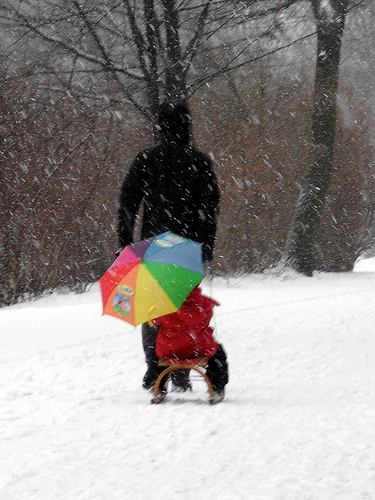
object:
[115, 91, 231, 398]
he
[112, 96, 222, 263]
jacket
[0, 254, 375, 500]
snow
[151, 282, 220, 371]
jacket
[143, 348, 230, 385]
pants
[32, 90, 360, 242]
snowfall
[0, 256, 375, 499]
ground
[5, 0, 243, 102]
trees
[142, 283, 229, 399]
child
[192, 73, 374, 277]
vegetation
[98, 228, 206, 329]
umbrella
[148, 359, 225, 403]
sled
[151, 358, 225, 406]
bench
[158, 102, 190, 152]
mask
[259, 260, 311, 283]
pile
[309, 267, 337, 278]
pile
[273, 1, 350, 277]
trunk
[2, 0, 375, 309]
bushes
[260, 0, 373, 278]
tree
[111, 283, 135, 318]
advertisement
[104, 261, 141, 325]
section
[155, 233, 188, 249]
advertisement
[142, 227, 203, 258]
section